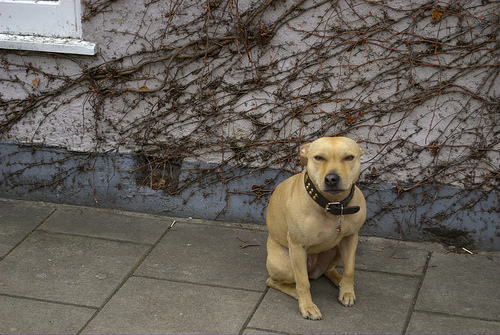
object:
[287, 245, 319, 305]
right leg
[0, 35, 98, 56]
window sill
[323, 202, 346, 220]
buckle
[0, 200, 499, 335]
sidewalk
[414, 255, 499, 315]
tile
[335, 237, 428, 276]
tile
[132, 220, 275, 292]
cement tile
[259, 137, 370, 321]
dog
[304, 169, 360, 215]
collar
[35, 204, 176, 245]
tile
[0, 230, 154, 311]
cement tile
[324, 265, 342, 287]
paw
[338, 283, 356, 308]
paw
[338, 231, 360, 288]
left leg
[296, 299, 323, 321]
paw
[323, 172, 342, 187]
nose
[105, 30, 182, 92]
vines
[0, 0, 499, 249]
building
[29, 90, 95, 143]
branch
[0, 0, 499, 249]
wall